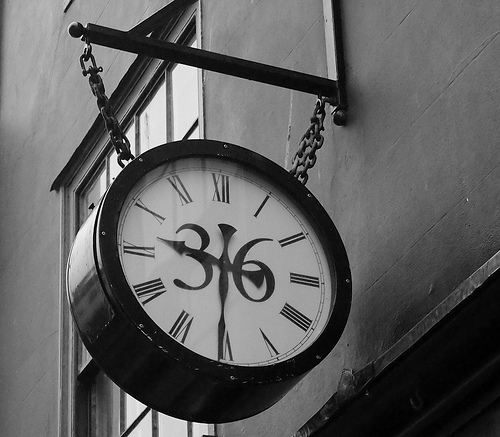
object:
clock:
[65, 139, 352, 423]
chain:
[79, 53, 131, 163]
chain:
[290, 106, 327, 180]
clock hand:
[156, 236, 265, 289]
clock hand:
[217, 223, 238, 363]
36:
[174, 221, 277, 304]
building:
[2, 2, 496, 435]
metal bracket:
[67, 0, 349, 126]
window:
[49, 1, 215, 436]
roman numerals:
[289, 271, 321, 289]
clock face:
[114, 154, 334, 367]